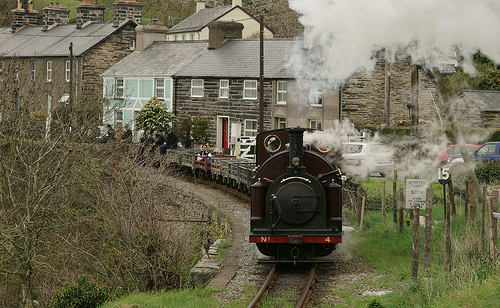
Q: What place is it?
A: It is a road.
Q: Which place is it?
A: It is a road.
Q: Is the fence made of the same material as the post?
A: Yes, both the fence and the post are made of wood.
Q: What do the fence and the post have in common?
A: The material, both the fence and the post are wooden.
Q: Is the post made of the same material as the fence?
A: Yes, both the post and the fence are made of wood.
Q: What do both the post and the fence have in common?
A: The material, both the post and the fence are wooden.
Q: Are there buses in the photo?
A: No, there are no buses.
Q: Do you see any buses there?
A: No, there are no buses.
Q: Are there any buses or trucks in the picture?
A: No, there are no buses or trucks.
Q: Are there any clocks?
A: No, there are no clocks.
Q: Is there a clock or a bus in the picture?
A: No, there are no clocks or buses.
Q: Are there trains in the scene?
A: Yes, there is a train.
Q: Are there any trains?
A: Yes, there is a train.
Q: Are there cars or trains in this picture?
A: Yes, there is a train.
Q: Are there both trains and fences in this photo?
A: Yes, there are both a train and a fence.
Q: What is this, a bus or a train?
A: This is a train.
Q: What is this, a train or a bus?
A: This is a train.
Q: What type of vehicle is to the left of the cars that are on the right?
A: The vehicle is a train.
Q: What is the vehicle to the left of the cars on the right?
A: The vehicle is a train.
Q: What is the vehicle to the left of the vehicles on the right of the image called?
A: The vehicle is a train.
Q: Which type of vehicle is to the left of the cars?
A: The vehicle is a train.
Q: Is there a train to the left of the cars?
A: Yes, there is a train to the left of the cars.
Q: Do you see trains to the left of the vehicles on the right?
A: Yes, there is a train to the left of the cars.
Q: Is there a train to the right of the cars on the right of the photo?
A: No, the train is to the left of the cars.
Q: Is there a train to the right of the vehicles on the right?
A: No, the train is to the left of the cars.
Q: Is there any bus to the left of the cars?
A: No, there is a train to the left of the cars.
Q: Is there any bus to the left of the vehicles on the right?
A: No, there is a train to the left of the cars.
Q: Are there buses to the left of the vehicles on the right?
A: No, there is a train to the left of the cars.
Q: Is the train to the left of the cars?
A: Yes, the train is to the left of the cars.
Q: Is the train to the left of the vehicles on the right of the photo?
A: Yes, the train is to the left of the cars.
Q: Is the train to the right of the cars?
A: No, the train is to the left of the cars.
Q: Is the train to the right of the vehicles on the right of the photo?
A: No, the train is to the left of the cars.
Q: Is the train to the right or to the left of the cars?
A: The train is to the left of the cars.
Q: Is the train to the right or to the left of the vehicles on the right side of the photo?
A: The train is to the left of the cars.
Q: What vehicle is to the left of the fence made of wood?
A: The vehicle is a train.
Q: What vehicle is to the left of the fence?
A: The vehicle is a train.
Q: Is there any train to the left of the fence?
A: Yes, there is a train to the left of the fence.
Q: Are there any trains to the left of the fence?
A: Yes, there is a train to the left of the fence.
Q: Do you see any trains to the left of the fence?
A: Yes, there is a train to the left of the fence.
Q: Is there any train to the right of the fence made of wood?
A: No, the train is to the left of the fence.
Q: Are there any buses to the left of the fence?
A: No, there is a train to the left of the fence.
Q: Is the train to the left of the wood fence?
A: Yes, the train is to the left of the fence.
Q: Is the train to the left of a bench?
A: No, the train is to the left of the fence.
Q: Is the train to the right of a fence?
A: No, the train is to the left of a fence.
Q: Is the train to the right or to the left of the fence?
A: The train is to the left of the fence.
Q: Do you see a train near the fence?
A: Yes, there is a train near the fence.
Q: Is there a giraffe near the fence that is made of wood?
A: No, there is a train near the fence.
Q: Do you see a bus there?
A: No, there are no buses.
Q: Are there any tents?
A: No, there are no tents.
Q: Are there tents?
A: No, there are no tents.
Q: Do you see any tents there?
A: No, there are no tents.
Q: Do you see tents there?
A: No, there are no tents.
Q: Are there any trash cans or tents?
A: No, there are no tents or trash cans.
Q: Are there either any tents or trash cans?
A: No, there are no tents or trash cans.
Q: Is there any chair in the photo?
A: No, there are no chairs.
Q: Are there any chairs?
A: No, there are no chairs.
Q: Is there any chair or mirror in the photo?
A: No, there are no chairs or mirrors.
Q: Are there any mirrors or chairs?
A: No, there are no chairs or mirrors.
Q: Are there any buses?
A: No, there are no buses.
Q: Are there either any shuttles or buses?
A: No, there are no buses or shuttles.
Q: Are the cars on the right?
A: Yes, the cars are on the right of the image.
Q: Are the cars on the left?
A: No, the cars are on the right of the image.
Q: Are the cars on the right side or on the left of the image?
A: The cars are on the right of the image.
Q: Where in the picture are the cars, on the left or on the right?
A: The cars are on the right of the image.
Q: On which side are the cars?
A: The cars are on the right of the image.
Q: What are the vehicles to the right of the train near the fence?
A: The vehicles are cars.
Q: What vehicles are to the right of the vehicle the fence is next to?
A: The vehicles are cars.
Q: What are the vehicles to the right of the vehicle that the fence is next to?
A: The vehicles are cars.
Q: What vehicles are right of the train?
A: The vehicles are cars.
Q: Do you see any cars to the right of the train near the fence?
A: Yes, there are cars to the right of the train.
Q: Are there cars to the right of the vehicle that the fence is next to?
A: Yes, there are cars to the right of the train.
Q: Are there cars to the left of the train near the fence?
A: No, the cars are to the right of the train.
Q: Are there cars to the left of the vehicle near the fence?
A: No, the cars are to the right of the train.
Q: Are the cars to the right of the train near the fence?
A: Yes, the cars are to the right of the train.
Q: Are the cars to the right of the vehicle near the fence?
A: Yes, the cars are to the right of the train.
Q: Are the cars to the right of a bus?
A: No, the cars are to the right of the train.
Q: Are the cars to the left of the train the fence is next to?
A: No, the cars are to the right of the train.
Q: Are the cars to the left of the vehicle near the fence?
A: No, the cars are to the right of the train.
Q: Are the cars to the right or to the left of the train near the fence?
A: The cars are to the right of the train.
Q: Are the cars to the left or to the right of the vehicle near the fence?
A: The cars are to the right of the train.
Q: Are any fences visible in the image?
A: Yes, there is a fence.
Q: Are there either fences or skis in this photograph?
A: Yes, there is a fence.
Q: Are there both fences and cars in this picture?
A: Yes, there are both a fence and a car.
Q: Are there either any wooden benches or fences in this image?
A: Yes, there is a wood fence.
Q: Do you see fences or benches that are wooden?
A: Yes, the fence is wooden.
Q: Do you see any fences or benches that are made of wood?
A: Yes, the fence is made of wood.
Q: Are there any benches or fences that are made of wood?
A: Yes, the fence is made of wood.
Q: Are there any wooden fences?
A: Yes, there is a wood fence.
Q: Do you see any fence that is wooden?
A: Yes, there is a fence that is wooden.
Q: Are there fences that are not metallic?
A: Yes, there is a wooden fence.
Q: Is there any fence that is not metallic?
A: Yes, there is a wooden fence.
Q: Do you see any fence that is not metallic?
A: Yes, there is a wooden fence.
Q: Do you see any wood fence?
A: Yes, there is a fence that is made of wood.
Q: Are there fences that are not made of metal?
A: Yes, there is a fence that is made of wood.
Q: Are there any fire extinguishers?
A: No, there are no fire extinguishers.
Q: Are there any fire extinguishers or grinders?
A: No, there are no fire extinguishers or grinders.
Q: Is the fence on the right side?
A: Yes, the fence is on the right of the image.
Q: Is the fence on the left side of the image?
A: No, the fence is on the right of the image.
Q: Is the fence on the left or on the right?
A: The fence is on the right of the image.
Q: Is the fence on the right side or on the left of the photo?
A: The fence is on the right of the image.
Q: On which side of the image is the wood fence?
A: The fence is on the right of the image.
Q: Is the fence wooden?
A: Yes, the fence is wooden.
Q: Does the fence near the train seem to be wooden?
A: Yes, the fence is wooden.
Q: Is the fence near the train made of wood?
A: Yes, the fence is made of wood.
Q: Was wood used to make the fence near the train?
A: Yes, the fence is made of wood.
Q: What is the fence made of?
A: The fence is made of wood.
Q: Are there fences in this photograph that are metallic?
A: No, there is a fence but it is wooden.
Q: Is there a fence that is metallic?
A: No, there is a fence but it is wooden.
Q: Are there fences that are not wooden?
A: No, there is a fence but it is wooden.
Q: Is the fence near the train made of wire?
A: No, the fence is made of wood.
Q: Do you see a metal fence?
A: No, there is a fence but it is made of wood.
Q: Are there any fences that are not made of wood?
A: No, there is a fence but it is made of wood.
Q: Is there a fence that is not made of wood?
A: No, there is a fence but it is made of wood.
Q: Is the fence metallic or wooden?
A: The fence is wooden.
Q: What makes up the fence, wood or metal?
A: The fence is made of wood.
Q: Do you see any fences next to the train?
A: Yes, there is a fence next to the train.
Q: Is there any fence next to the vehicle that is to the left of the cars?
A: Yes, there is a fence next to the train.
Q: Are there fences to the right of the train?
A: Yes, there is a fence to the right of the train.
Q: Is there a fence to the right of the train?
A: Yes, there is a fence to the right of the train.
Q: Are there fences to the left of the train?
A: No, the fence is to the right of the train.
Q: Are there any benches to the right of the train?
A: No, there is a fence to the right of the train.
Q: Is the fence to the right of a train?
A: Yes, the fence is to the right of a train.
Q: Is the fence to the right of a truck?
A: No, the fence is to the right of a train.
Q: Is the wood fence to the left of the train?
A: No, the fence is to the right of the train.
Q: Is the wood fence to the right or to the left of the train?
A: The fence is to the right of the train.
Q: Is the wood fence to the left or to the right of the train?
A: The fence is to the right of the train.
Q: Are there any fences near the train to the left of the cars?
A: Yes, there is a fence near the train.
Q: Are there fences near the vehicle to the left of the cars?
A: Yes, there is a fence near the train.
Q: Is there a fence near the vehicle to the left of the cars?
A: Yes, there is a fence near the train.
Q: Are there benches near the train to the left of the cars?
A: No, there is a fence near the train.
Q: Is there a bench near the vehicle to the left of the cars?
A: No, there is a fence near the train.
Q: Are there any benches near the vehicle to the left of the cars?
A: No, there is a fence near the train.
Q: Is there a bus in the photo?
A: No, there are no buses.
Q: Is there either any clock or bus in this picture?
A: No, there are no buses or clocks.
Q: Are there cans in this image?
A: No, there are no cans.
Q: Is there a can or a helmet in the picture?
A: No, there are no cans or helmets.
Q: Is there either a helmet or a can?
A: No, there are no cans or helmets.